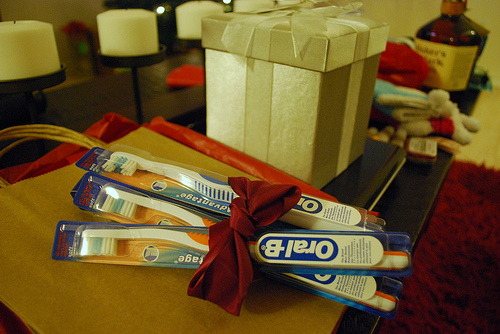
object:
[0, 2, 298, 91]
candles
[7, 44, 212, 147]
candle holders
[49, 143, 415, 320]
toothbrushes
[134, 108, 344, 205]
tissue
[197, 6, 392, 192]
gift box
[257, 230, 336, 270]
brand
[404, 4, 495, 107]
liquor bottle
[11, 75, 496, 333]
table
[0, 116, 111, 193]
handles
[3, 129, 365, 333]
gift bags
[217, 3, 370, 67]
bow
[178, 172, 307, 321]
red bow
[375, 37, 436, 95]
clothing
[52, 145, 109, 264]
background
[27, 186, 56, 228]
paper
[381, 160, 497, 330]
rug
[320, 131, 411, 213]
laptop